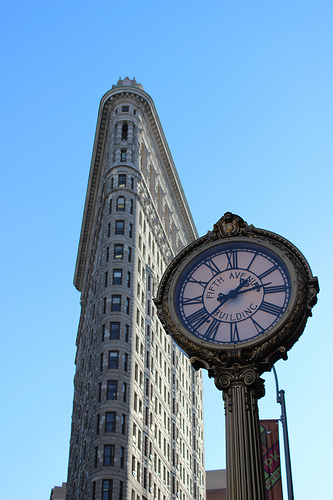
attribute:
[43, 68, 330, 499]
building — in the picture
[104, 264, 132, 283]
window — in the picture